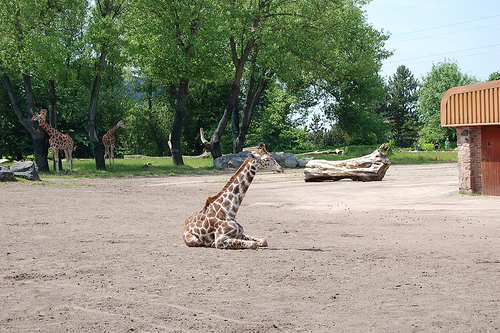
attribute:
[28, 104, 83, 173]
giraffe — brown, white, yellow, spotted, standing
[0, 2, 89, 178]
tree — standing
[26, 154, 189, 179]
grass — green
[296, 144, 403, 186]
tree stump — large, brown, wooden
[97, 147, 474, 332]
ground — tan, dirt, sandy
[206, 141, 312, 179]
rocks — large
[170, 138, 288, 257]
giraffe — resting, looking, sitting, lying down, brown, white, sleeping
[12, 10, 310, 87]
leaves — green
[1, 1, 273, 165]
trees — brown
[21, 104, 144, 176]
giraffes — standing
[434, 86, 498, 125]
roof — orange, ridged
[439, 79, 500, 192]
building — brick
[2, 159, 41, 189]
rocks — grey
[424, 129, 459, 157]
people — looking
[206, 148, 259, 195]
mane — brown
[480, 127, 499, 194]
door — red